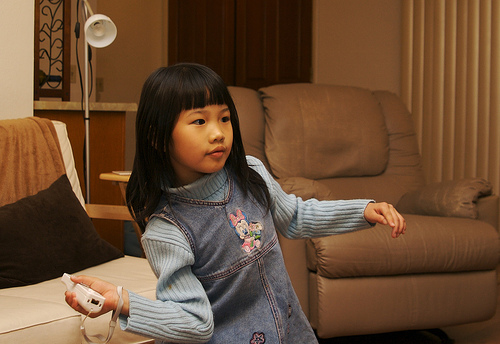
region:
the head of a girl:
[145, 76, 247, 176]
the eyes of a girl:
[179, 95, 255, 134]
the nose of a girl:
[206, 122, 251, 159]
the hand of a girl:
[351, 190, 404, 233]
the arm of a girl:
[243, 105, 493, 239]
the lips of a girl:
[183, 137, 251, 193]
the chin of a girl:
[181, 160, 252, 222]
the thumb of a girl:
[79, 262, 122, 314]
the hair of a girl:
[109, 60, 260, 200]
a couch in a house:
[213, 68, 443, 319]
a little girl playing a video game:
[58, 60, 408, 342]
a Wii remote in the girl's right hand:
[55, 271, 105, 318]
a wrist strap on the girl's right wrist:
[111, 283, 128, 325]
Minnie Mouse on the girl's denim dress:
[226, 208, 256, 251]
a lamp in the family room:
[72, 0, 117, 205]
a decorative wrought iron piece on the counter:
[35, 0, 72, 102]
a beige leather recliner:
[222, 79, 498, 342]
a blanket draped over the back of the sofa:
[0, 115, 128, 295]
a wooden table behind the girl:
[92, 167, 132, 201]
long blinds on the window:
[397, 0, 498, 191]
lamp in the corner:
[78, 15, 116, 60]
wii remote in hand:
[46, 278, 102, 312]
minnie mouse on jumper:
[218, 205, 277, 261]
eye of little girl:
[184, 116, 204, 131]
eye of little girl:
[214, 112, 235, 127]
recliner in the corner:
[268, 72, 484, 320]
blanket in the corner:
[15, 123, 99, 270]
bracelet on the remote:
[102, 285, 132, 335]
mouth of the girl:
[206, 150, 229, 165]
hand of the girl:
[367, 191, 404, 229]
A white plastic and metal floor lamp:
[78, 8, 125, 192]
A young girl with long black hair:
[131, 68, 276, 265]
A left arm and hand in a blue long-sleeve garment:
[293, 196, 410, 239]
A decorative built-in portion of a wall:
[36, 8, 69, 96]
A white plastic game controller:
[58, 267, 114, 326]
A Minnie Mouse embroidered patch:
[212, 208, 276, 263]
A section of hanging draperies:
[415, 10, 491, 158]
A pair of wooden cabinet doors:
[180, 6, 300, 62]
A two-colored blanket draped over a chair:
[7, 130, 102, 272]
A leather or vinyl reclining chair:
[271, 88, 496, 325]